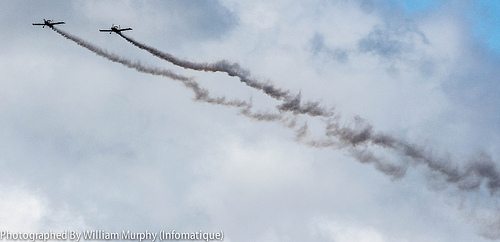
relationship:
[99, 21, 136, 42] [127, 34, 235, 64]
plane leaves trail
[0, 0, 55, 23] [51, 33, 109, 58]
dark spot leaves trail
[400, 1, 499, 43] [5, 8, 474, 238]
blue spot in sky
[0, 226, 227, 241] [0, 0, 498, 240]
tag at bottom of image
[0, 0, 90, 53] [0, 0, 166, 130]
dark spot at top left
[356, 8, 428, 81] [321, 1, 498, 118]
wispy cloud at top right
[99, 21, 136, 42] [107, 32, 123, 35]
plane has out wheels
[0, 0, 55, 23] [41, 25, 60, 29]
dark spot has out wheels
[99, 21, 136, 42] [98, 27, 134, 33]
plane has wings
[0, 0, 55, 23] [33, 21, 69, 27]
dark spot has wings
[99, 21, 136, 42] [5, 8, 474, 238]
plane in sky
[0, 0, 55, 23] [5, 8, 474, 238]
dark spot in sky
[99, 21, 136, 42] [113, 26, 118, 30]
plane has engine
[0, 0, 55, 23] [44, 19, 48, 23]
dark spot has engine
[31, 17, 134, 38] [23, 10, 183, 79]
planes in dogfight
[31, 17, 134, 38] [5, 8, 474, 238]
planes in sky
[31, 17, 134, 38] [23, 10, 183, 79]
planes in flight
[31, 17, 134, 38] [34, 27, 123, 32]
planes have gear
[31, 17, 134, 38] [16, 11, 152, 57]
piper cubs flying together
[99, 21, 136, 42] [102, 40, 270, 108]
airplane with smoke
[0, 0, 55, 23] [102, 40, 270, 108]
dark spot with smoke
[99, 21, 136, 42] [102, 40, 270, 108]
plane with smoke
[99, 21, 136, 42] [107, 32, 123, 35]
airplane with wheels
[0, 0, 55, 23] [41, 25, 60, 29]
dark spot with wheels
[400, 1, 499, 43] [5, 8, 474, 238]
sky through clouds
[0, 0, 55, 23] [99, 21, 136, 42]
dark spot in front of plane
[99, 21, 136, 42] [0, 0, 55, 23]
plane near dark spot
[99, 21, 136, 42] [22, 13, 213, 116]
plane in air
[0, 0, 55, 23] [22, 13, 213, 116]
dark spot in air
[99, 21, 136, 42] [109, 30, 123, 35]
plane has legs down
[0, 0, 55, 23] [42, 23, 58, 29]
dark spot has legs down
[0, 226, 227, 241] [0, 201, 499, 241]
words are at bottom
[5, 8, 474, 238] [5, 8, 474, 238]
sky with clouds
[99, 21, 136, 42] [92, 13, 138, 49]
plane behind plane